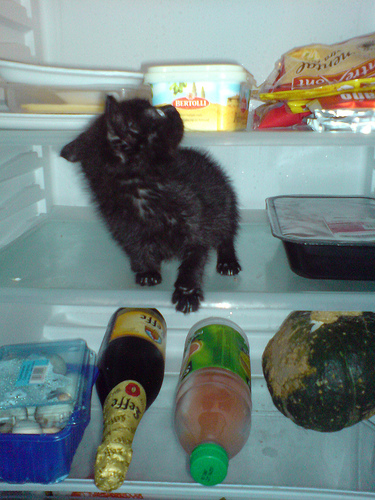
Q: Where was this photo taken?
A: Fridge.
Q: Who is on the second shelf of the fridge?
A: Cat.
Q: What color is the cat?
A: Black.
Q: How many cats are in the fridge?
A: One.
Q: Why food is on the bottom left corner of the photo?
A: Mushrooms.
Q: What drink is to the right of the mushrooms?
A: Seffe beer.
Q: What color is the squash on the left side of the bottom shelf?
A: Green.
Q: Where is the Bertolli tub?
A: Top shelf.